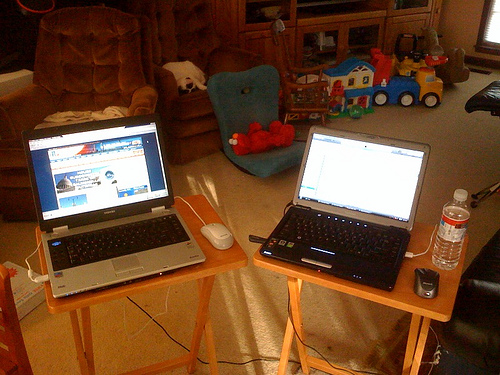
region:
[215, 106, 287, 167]
Toy sitting in the floor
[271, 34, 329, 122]
Toy sitting in the floor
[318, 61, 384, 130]
Toy sitting in the floor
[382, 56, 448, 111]
Toy sitting in the floor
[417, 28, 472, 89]
Toy sitting in the floor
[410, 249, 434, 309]
MOuse on computer desk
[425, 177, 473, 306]
Bottle of water on desk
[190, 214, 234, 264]
White mouse on desk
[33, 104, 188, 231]
Screen of a computer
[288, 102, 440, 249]
Screen of a computer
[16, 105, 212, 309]
laptop computer powered on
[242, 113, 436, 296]
laptop computer powered on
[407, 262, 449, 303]
mouse to a laptop computer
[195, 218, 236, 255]
mouse to a laptop computer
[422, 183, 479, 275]
water bottle near a computer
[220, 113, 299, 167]
red stuffed animal in the room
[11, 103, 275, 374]
latop computer on a stand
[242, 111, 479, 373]
latop computer on a stand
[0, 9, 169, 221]
brown stuffed reclining chair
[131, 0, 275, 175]
brown stuffed reclining chair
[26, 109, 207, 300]
laptop on the left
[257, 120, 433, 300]
laptop on the right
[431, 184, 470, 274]
water bottle next to laptop on the right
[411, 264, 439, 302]
mouse next to laptop on the right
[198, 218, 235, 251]
mouse next to laptop on the left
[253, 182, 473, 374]
TV table that has the laptop on the right on it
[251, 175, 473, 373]
tv table that the right laptop is sitting on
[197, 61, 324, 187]
blue game chair sitting in floor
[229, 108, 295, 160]
tickle me elmo in game chair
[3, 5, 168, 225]
older model chair sitting in corner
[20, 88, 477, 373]
two laptops on a portable table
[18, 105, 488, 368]
two laptops with a computer mouse attached to it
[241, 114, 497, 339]
water bottle near laptop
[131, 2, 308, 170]
brown chair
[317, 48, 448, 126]
Toys on the floor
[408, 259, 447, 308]
black and silver computer mouse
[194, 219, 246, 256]
white and grey computer mouse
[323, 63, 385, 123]
blue and white toy house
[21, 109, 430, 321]
two laptops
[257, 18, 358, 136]
small wooden rocking chair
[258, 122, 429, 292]
Opened lap top computer turned on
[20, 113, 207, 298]
Laptop computer sitting on a TV tray stand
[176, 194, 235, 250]
White computer mouse with cord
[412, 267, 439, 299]
Wireless mouse for computer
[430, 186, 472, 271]
Bottle of water sitting on a TV tray stand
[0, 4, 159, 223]
Large brown reclining chair in the living room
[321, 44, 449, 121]
Children's toys sitting on the floor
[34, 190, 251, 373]
Collapsible TV tray stand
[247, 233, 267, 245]
Flash drive plugged into a laptop computer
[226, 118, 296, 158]
Stuffed animal sitting in a chair